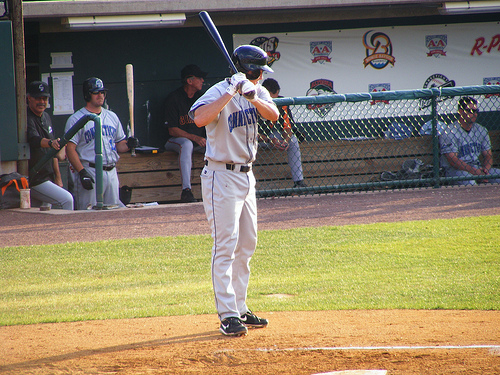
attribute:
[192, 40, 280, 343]
glove — white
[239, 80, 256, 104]
glove — white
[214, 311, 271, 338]
shoe — black, white, cleat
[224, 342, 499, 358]
line — white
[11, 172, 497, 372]
field — baseball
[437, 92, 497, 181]
baseball player — seated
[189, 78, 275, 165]
baseball jersey — grey, blue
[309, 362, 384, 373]
home plate — white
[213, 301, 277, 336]
shoe — black, white, cleat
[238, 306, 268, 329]
shoe — black, Nike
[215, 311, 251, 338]
shoe — black, Nike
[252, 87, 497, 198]
dugout railing — green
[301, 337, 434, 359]
line — white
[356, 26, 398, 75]
logo — team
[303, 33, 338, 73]
logo — team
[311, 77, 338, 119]
logo — team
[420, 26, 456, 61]
logo — team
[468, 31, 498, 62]
logo — team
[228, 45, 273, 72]
helmet — dark blue, protective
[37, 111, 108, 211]
handrail — green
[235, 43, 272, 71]
helmet — black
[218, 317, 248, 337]
shoe — black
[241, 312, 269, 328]
shoe — black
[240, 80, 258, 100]
glove — white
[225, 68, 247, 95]
glove — white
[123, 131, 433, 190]
bench — long, wooden